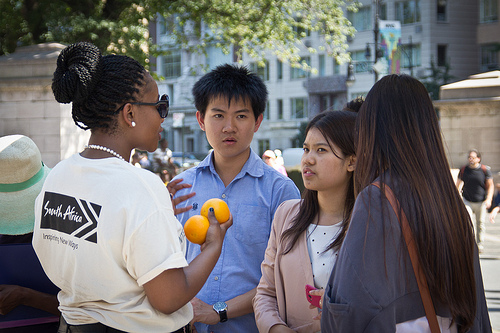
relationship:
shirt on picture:
[42, 142, 182, 330] [37, 182, 105, 242]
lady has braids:
[30, 42, 233, 332] [70, 52, 155, 128]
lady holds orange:
[30, 42, 233, 332] [181, 212, 211, 246]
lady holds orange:
[30, 42, 233, 332] [198, 196, 232, 225]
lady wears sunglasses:
[30, 42, 233, 332] [131, 86, 176, 113]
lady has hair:
[320, 73, 491, 333] [343, 76, 492, 325]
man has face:
[169, 66, 302, 333] [201, 88, 258, 159]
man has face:
[169, 66, 302, 333] [202, 100, 259, 155]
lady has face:
[30, 42, 233, 332] [122, 65, 171, 154]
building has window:
[130, 3, 449, 187] [160, 58, 181, 76]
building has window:
[130, 3, 449, 187] [287, 58, 310, 78]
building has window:
[130, 3, 449, 187] [156, 13, 175, 35]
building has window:
[130, 3, 449, 187] [277, 55, 283, 81]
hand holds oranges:
[198, 206, 233, 253] [182, 196, 229, 243]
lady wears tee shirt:
[30, 37, 242, 325] [17, 149, 245, 329]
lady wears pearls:
[30, 42, 233, 332] [71, 131, 127, 170]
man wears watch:
[169, 66, 302, 333] [212, 300, 229, 322]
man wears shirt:
[148, 60, 305, 331] [173, 158, 293, 325]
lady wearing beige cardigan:
[256, 113, 354, 330] [252, 197, 322, 329]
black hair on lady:
[343, 74, 477, 330] [360, 84, 472, 288]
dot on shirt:
[322, 228, 326, 233] [303, 220, 341, 294]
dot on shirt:
[310, 234, 315, 244] [303, 220, 341, 294]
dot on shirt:
[315, 250, 320, 255] [303, 220, 341, 294]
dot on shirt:
[322, 262, 329, 266] [303, 220, 341, 294]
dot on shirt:
[335, 251, 338, 258] [303, 220, 341, 294]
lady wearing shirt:
[256, 113, 354, 330] [303, 220, 341, 294]